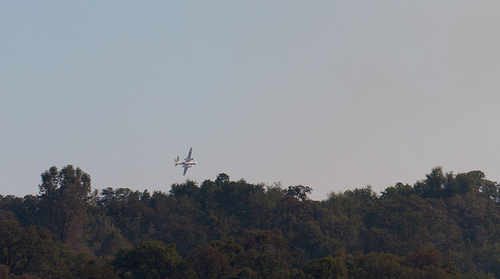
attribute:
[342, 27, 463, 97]
clouds — white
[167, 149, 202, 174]
plane — white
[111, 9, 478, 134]
sky — blue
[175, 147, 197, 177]
plane — white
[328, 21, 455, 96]
clouds — white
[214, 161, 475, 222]
trees — tall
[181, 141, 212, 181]
airplane — high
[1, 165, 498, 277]
forest — green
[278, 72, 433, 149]
skies — clear, blue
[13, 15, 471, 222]
sky — blue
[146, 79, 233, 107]
cloud — white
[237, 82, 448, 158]
clouds — white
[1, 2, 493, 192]
sky — blue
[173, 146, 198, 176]
airplane — mid air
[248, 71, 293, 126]
clouds — white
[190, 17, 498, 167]
clouds — white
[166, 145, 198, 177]
plane — white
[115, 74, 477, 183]
sky — blue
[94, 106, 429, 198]
sky — blue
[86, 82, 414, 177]
sky — blue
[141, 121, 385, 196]
sky — blue